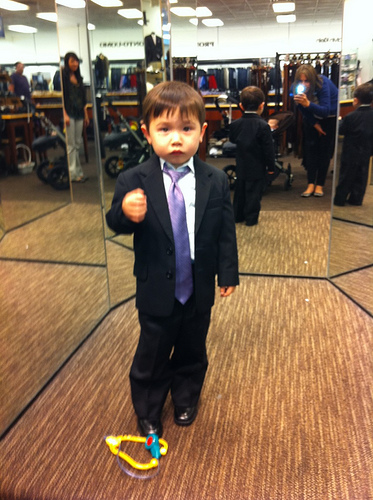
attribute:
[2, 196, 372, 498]
carpet — brown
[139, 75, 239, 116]
hair — black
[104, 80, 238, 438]
boy — little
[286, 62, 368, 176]
woman — blonde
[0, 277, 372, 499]
carpet — brown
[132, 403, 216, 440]
shoes — dress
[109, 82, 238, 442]
child — small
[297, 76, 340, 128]
sweater — blue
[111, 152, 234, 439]
suit — black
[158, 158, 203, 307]
tie — indigo colored